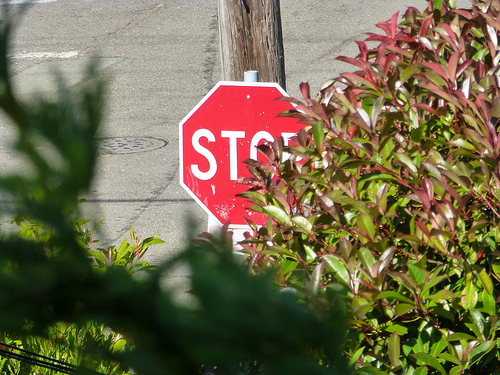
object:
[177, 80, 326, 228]
sign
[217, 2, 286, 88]
pole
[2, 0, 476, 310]
road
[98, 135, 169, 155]
manhole cover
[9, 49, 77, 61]
line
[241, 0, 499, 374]
bush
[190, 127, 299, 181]
stop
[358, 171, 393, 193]
leaf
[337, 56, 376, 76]
leaf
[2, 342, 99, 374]
electric line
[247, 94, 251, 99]
bolt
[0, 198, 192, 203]
shadow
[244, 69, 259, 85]
pole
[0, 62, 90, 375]
tree